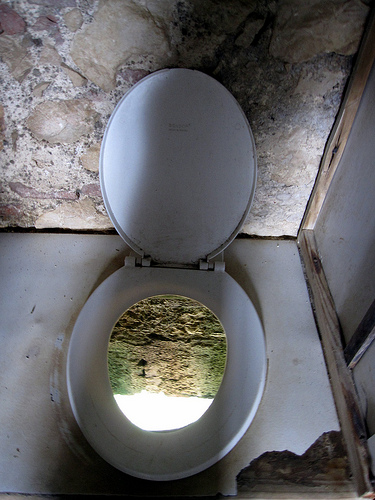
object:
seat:
[61, 257, 271, 487]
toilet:
[67, 63, 279, 487]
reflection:
[93, 77, 153, 225]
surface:
[24, 320, 71, 413]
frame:
[299, 222, 326, 277]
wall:
[0, 0, 372, 241]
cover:
[98, 65, 258, 268]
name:
[168, 121, 191, 133]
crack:
[262, 444, 327, 494]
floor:
[0, 235, 352, 499]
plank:
[344, 301, 375, 371]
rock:
[45, 0, 81, 40]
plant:
[108, 337, 134, 394]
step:
[123, 242, 227, 278]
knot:
[129, 353, 147, 371]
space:
[7, 230, 54, 252]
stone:
[123, 250, 226, 274]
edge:
[223, 266, 251, 301]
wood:
[339, 395, 364, 446]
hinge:
[125, 252, 151, 270]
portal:
[103, 293, 227, 434]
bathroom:
[0, 0, 374, 498]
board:
[234, 428, 356, 494]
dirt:
[156, 227, 186, 253]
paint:
[47, 367, 86, 426]